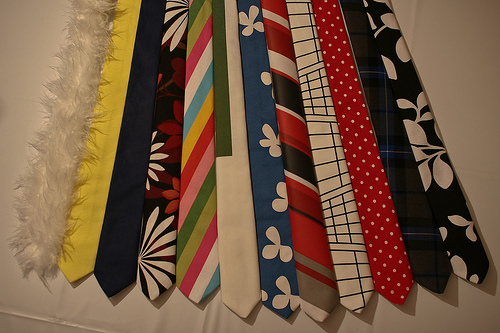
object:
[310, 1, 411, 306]
necktie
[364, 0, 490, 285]
necktie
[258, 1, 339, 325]
necktie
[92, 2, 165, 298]
black tie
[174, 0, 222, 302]
tie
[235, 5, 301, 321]
blue necktie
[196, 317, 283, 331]
cloth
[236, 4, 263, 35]
white flowers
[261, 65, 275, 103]
white flowers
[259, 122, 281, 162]
white flowers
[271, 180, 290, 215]
white flowers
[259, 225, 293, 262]
white flowers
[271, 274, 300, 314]
white flowers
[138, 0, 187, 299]
necktie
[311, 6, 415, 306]
necktie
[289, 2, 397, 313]
tie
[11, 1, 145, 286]
necktie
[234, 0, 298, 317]
tie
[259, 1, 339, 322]
tie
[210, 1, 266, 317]
tie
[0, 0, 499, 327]
background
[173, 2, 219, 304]
necktie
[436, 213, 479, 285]
object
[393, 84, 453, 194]
object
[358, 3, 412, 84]
object